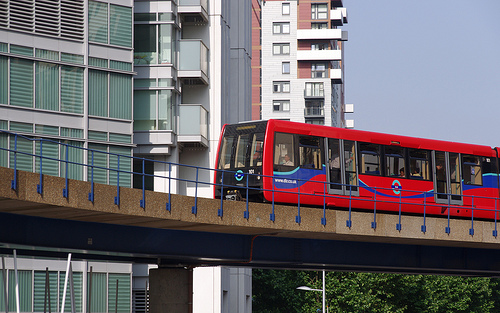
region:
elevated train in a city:
[4, 120, 493, 280]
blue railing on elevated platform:
[33, 136, 256, 207]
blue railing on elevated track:
[31, 138, 216, 209]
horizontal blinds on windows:
[2, 3, 85, 50]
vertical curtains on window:
[31, 61, 56, 121]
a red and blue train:
[212, 121, 499, 221]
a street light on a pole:
[292, 276, 327, 310]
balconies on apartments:
[294, 21, 350, 81]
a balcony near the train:
[173, 78, 210, 140]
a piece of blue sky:
[344, 0, 498, 125]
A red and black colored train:
[198, 103, 499, 242]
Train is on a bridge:
[155, 108, 498, 295]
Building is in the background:
[1, 1, 358, 185]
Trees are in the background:
[259, 268, 499, 312]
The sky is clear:
[352, 0, 498, 144]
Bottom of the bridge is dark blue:
[11, 215, 498, 272]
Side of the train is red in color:
[260, 108, 498, 226]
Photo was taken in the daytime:
[3, 3, 498, 310]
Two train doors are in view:
[316, 136, 466, 211]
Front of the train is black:
[211, 116, 268, 200]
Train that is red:
[204, 111, 498, 226]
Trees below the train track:
[251, 267, 499, 307]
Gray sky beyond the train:
[348, 5, 498, 138]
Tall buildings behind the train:
[0, 0, 345, 128]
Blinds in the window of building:
[5, 5, 125, 145]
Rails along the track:
[0, 160, 305, 217]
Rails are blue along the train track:
[5, 160, 365, 225]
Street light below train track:
[293, 266, 339, 308]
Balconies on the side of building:
[174, 1, 216, 151]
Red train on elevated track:
[201, 94, 496, 240]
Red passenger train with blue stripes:
[209, 99, 498, 226]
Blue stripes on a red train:
[219, 151, 499, 203]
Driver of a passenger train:
[275, 132, 296, 176]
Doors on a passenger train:
[317, 119, 364, 208]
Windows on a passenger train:
[350, 126, 445, 191]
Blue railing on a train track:
[12, 124, 497, 251]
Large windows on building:
[5, 41, 140, 311]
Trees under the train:
[243, 253, 489, 312]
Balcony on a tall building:
[167, 37, 218, 160]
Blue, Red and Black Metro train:
[228, 115, 478, 210]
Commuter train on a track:
[191, 107, 347, 242]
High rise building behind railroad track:
[58, 26, 193, 274]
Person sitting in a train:
[393, 162, 422, 173]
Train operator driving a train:
[271, 147, 299, 168]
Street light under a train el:
[276, 267, 368, 311]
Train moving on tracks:
[216, 113, 394, 217]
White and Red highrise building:
[256, 3, 358, 114]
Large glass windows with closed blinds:
[8, 45, 173, 135]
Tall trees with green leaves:
[283, 271, 451, 309]